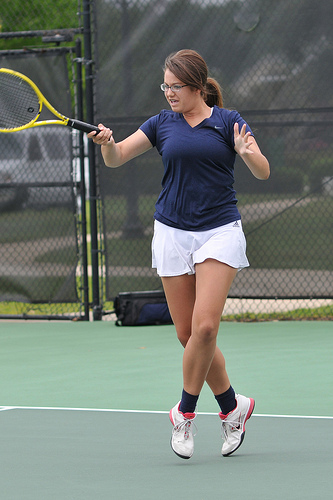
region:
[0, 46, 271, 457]
Young woman playing tennis.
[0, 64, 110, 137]
Yellow and black tennis racquet.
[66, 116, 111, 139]
Black handle of a tennis racquet.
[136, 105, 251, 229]
Young woman wearing a blue shirt.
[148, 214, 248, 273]
A woman wearing white shorts.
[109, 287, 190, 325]
A black and blue bag near the fence.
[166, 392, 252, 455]
Pink and white tennis shoes.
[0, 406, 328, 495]
Dark green tennis court boundary.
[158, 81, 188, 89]
A young woman wearing glasses.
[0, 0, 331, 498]
Metal fence covered in netting.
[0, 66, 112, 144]
Yellow tennis racket with black handle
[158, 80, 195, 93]
Girl is wearing glasses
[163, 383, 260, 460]
Pink and white shoes with blue socks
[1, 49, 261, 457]
Young girl holding tennis racket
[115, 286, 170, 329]
Blue and black sports bag in the background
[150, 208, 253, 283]
White Adidas tennis skirt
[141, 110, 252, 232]
Blue Nike tennis shirt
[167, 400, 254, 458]
White and pink Nike shoes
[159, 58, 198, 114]
Young girl has grimace on her face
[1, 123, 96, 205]
White van behind the gate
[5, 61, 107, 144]
yellow tennis racket on left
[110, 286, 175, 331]
blue bag against fence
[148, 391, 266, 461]
pink and white tennis shoes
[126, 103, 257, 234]
blue top on woman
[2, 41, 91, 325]
metal fence-type gate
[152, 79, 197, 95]
glasses on woman's face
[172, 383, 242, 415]
black socks on woman's feet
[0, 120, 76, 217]
white vehicle in background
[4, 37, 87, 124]
tree in backgroung on left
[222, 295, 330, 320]
sidewalk outside fence on right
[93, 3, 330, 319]
chain link fence around the tennis court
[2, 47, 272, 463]
girl playing tennis making a strange face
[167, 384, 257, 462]
girl wearing white and pink tennis shoes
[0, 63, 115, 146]
someone holding a tennis racket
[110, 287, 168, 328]
duffle bag sitting on the ground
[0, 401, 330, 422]
lines marked on the tennis court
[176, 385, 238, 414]
person wearing black socks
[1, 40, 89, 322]
gate for the chain link fence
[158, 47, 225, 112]
girl wearing her hair in a ponytail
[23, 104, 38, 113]
hole in the tennis racket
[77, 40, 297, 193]
lady on a court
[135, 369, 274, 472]
two shoes on the feet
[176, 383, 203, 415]
sock on the person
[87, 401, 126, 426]
white line on the court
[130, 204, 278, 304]
skirt on the lady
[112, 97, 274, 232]
blue shirt on the lady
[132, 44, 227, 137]
head of the girl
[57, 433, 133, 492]
blue court under lady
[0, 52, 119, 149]
racket in girl's hand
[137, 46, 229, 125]
glasses on woman's face